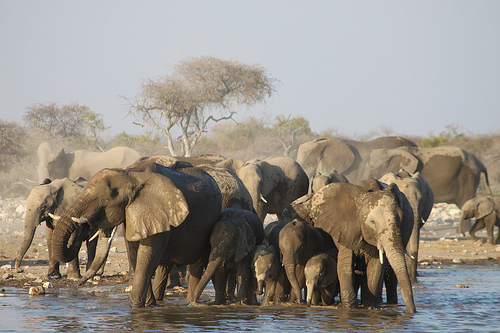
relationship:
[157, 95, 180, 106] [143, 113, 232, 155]
leaves attached to tree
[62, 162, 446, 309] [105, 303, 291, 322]
elephants in water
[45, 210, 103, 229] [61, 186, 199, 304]
tusks attached to elephant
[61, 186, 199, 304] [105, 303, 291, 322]
elephant next to water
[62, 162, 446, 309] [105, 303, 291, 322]
elephants on top of water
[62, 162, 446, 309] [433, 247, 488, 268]
elephants on top of ground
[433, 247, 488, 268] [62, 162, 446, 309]
ground behind elephants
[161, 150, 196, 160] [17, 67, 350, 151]
trunks attached to trees